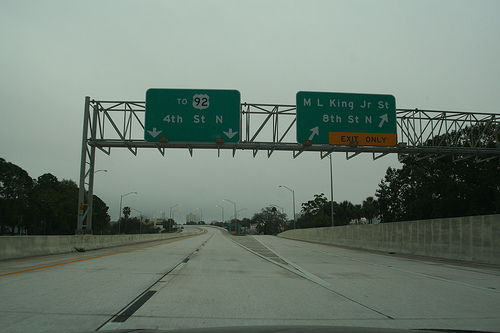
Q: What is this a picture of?
A: A part of a highway.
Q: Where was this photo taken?
A: At a highway junction of MLK Jr St and 4th street.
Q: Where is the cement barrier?
A: On either side of the road.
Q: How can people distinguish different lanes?
A: The black broken lines.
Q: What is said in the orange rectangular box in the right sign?
A: Exit only.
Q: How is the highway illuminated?
A: By the multiple light posts along the side of the highway.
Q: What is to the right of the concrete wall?
A: Trees.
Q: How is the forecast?
A: Mostly cloudy and grey skies.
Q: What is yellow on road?
A: Line.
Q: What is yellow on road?
A: Line.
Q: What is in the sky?
A: Clouds.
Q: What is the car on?
A: Highway.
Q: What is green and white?
A: Signs.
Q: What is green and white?
A: Signs.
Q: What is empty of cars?
A: Highway.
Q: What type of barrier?
A: Fence.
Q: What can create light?
A: Lamp post.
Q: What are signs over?
A: Highway.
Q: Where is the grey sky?
A: Over the green signs.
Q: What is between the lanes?
A: A triangular divide.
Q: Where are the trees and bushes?
A: Behind the low partition.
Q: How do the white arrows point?
A: Downwards and angled upwards.`.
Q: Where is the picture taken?
A: Highway.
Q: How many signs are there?
A: 2.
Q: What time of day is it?
A: Day time.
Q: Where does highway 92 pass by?
A: 4th St N.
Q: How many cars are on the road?
A: 0.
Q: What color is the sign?
A: Green.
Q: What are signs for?
A: Navigation.